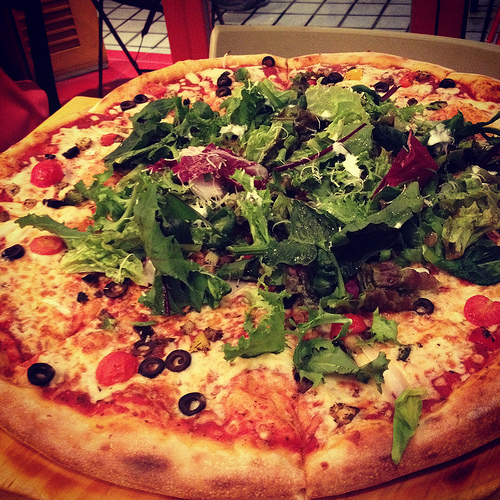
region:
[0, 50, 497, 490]
A large pizza in the image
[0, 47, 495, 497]
Pizza is fully cooked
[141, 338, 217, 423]
Pizza has black olives as topping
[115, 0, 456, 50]
The floor is made up of tiles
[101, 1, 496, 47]
The tiles are white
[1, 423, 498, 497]
Pizza is on a wooden board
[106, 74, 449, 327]
Pizza has eatable leafs on top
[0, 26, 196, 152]
A red rug is on the floor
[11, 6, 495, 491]
Photo was taken indoors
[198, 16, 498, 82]
The top of a chair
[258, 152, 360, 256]
green stuff on pizza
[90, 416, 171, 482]
brown crust on pizza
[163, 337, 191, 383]
black topping on pizza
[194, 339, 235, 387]
cheese on the pizza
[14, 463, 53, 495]
brown table below pizza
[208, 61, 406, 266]
many toppings on pizza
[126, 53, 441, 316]
round pizza on table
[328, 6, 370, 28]
tile on the ground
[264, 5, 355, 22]
square tiles on ground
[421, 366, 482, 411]
red sauce on pizza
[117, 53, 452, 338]
Green and purple salad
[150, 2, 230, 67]
Red column near table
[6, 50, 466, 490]
The pizza is round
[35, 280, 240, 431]
Black olives on pizza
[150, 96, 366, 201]
Grated cheese on salad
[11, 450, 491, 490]
Pizza is on top of table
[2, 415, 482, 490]
The table is wood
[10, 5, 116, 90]
Narrow brown wooden door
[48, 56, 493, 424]
The salad is on top of the pizza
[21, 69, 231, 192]
The pizza has red sauce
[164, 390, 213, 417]
black olive on pizza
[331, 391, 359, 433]
mushroom on pizza sitting on table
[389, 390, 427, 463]
spinach on pizza crust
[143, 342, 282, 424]
cheese and olives on piazza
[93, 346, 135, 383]
pepperoni on top of pizza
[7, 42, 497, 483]
spinach and purple lettuce and cheese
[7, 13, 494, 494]
pizza on top of a table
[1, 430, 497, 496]
brown table that pizza is sitting on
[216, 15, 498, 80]
back of a brown chair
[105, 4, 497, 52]
white tile floor with red railings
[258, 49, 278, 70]
a black olive on the pizza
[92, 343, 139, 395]
pepperoni on the pizza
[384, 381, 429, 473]
a green leaf of lettuce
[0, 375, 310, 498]
a brown pizza crust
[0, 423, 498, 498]
a brown wooden table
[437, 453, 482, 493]
a knot in the wood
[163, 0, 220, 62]
the leg of a table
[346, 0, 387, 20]
a white tile on the floor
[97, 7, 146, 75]
a black table leg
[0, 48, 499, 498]
a pizza on the table